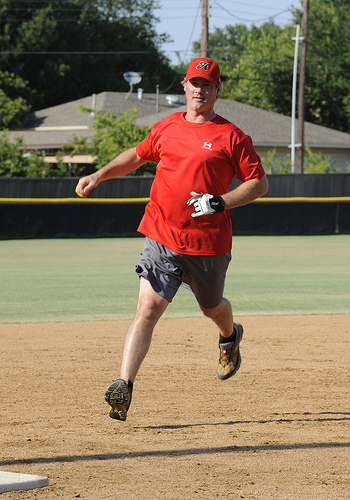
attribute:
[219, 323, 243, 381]
shoe — grey, orange, yellow, gray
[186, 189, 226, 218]
glove — sport's, black, white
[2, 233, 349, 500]
ground — sandy, grassy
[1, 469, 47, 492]
baseball base — white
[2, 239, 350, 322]
grass — green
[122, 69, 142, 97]
antenna — gray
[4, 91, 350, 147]
roof — gray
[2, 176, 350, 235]
fence — wooden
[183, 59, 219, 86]
cap — protective, red, orange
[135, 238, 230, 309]
shorts — gray, athletic, grey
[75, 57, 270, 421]
man — fat, jogging, running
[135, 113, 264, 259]
shirt — orange, red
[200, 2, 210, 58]
pole — wooden, electric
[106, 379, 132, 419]
foot — raised